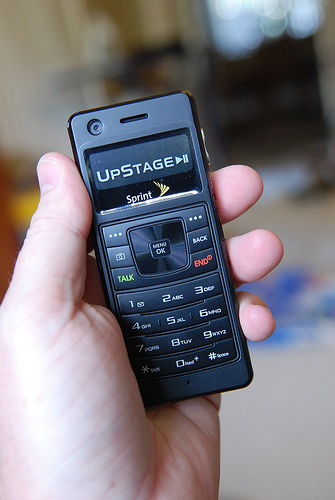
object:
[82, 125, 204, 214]
screen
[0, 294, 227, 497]
palm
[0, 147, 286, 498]
person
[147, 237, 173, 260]
button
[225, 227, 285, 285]
finger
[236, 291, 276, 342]
finger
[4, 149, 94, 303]
finger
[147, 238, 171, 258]
menu button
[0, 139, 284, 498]
hand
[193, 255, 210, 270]
end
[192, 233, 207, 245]
word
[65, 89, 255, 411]
phone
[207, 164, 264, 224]
middle finger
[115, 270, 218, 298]
limes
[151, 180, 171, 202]
brand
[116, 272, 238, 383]
keypad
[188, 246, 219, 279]
button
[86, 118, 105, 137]
camera